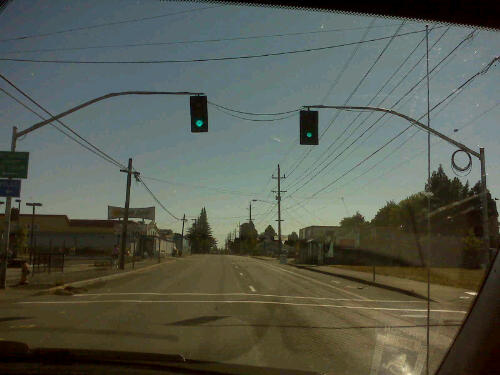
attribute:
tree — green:
[183, 184, 233, 295]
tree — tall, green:
[188, 207, 210, 258]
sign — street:
[5, 178, 21, 200]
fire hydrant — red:
[16, 262, 34, 294]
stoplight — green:
[287, 107, 335, 151]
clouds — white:
[199, 69, 354, 183]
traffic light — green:
[187, 91, 211, 135]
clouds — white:
[166, 162, 241, 214]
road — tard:
[50, 174, 475, 354]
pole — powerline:
[267, 155, 297, 266]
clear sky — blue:
[0, 0, 498, 246]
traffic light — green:
[299, 110, 318, 145]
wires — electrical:
[267, 29, 479, 191]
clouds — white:
[177, 158, 244, 200]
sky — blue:
[0, 0, 499, 206]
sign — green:
[282, 105, 348, 179]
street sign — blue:
[0, 180, 24, 198]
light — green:
[283, 109, 328, 156]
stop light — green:
[189, 93, 208, 133]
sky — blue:
[1, 1, 484, 247]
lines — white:
[19, 286, 469, 307]